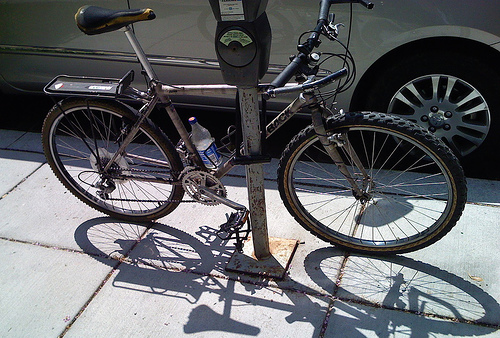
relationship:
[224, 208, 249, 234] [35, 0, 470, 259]
pedal of a bicycle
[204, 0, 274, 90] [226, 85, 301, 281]
parking meter has pole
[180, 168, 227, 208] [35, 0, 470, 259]
gear on a bicycle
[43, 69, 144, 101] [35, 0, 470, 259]
rack on a bicycle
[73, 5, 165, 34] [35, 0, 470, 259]
seat of a bicycle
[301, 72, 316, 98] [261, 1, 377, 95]
brake on handle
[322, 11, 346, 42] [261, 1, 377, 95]
brake on handle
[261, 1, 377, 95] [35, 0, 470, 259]
handle of a bicycle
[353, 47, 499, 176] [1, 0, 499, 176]
wheel of a car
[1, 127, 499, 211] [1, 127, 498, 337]
shadow on sidewalk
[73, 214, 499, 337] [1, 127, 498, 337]
shadow on sidewalk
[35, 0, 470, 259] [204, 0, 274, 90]
bicycle secured to parking meter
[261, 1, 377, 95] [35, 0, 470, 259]
handle of bicycle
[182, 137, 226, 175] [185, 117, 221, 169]
drink holder with a bottle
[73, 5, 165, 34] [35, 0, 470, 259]
seat of bicycle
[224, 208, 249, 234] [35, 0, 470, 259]
pedal of bicycle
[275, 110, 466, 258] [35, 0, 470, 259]
front wheel of bicycle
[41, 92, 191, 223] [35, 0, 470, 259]
rear wheel of bicycle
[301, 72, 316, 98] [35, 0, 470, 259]
brake on bicycle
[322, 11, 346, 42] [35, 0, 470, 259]
brake on bicycle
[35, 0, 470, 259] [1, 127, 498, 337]
bicycle on sidewalk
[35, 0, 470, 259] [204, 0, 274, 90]
bicycle leaning on parking meter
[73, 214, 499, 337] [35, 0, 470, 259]
shadow of bicycle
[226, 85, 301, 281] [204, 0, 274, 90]
pole of parking meter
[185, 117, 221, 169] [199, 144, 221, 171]
bottle for water